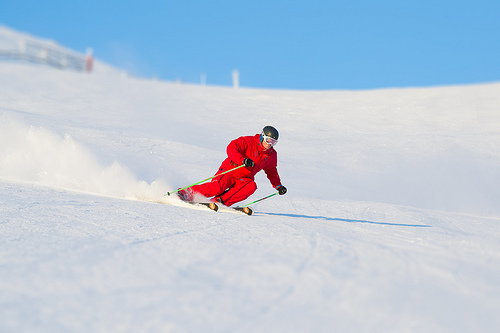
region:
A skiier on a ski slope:
[0, 22, 497, 330]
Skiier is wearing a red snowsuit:
[178, 123, 288, 217]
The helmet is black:
[260, 120, 282, 140]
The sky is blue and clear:
[2, 1, 499, 88]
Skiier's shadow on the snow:
[247, 204, 435, 234]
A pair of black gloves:
[237, 153, 290, 197]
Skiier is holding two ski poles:
[177, 120, 290, 214]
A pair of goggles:
[258, 131, 279, 149]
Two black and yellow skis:
[186, 196, 258, 218]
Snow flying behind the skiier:
[16, 123, 180, 206]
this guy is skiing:
[146, 96, 336, 231]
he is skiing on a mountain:
[130, 63, 333, 250]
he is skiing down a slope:
[134, 54, 354, 234]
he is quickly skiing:
[90, 81, 344, 241]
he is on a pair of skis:
[107, 41, 352, 279]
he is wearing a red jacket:
[125, 70, 332, 265]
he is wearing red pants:
[122, 65, 390, 236]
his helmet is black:
[227, 96, 305, 183]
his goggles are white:
[247, 128, 294, 153]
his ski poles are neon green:
[136, 149, 323, 229]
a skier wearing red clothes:
[171, 118, 291, 223]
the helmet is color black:
[248, 118, 285, 157]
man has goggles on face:
[261, 132, 278, 147]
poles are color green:
[161, 162, 279, 209]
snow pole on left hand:
[241, 183, 290, 210]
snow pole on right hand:
[161, 155, 247, 205]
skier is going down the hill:
[159, 100, 421, 311]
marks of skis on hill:
[80, 214, 420, 331]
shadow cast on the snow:
[263, 203, 441, 232]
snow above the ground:
[3, 111, 171, 206]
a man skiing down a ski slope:
[99, 87, 289, 227]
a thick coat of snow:
[11, 215, 497, 327]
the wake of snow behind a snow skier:
[5, 107, 187, 218]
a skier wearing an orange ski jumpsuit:
[166, 115, 291, 220]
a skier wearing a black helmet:
[255, 122, 280, 154]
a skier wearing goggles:
[263, 132, 278, 150]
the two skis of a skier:
[176, 190, 268, 229]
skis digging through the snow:
[176, 187, 267, 227]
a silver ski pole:
[152, 164, 244, 199]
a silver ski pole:
[243, 193, 278, 223]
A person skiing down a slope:
[155, 120, 293, 220]